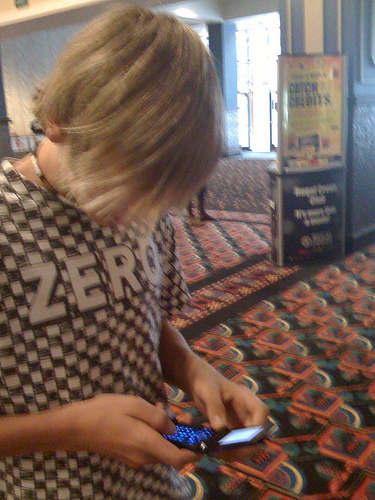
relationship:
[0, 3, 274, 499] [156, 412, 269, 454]
boy holding cell phone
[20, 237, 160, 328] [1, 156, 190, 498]
word on shirt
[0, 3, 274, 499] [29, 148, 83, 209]
boy wearing necklace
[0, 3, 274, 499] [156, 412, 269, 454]
boy using cell phone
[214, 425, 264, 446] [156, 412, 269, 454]
screen of cell phone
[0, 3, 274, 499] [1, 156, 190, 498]
boy wearing shirt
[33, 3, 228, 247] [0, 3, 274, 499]
hair of boy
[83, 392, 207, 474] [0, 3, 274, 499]
hand of boy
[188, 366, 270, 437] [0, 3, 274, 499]
hand of boy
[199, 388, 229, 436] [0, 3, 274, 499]
thumb of boy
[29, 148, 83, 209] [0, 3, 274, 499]
necklace on boy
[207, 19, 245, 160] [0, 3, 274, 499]
molding behind boy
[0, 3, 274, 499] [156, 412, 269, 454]
boy has cell phone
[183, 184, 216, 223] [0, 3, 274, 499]
legs behind boy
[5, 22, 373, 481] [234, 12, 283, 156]
building has entry